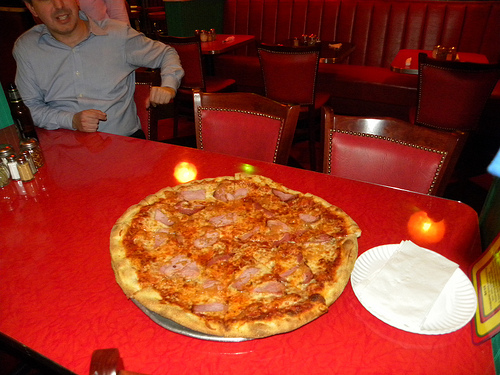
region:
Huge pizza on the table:
[94, 148, 367, 354]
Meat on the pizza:
[159, 214, 263, 295]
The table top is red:
[16, 233, 177, 357]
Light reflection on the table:
[395, 184, 478, 259]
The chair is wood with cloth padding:
[312, 98, 462, 178]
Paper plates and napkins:
[358, 228, 472, 338]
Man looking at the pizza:
[22, 3, 199, 176]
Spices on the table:
[9, 128, 56, 180]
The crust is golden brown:
[263, 295, 327, 332]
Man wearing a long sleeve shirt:
[42, 30, 142, 101]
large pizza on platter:
[132, 156, 321, 371]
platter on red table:
[126, 179, 325, 356]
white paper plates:
[372, 227, 454, 321]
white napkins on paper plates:
[368, 252, 452, 319]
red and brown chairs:
[210, 79, 465, 189]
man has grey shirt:
[0, 16, 166, 137]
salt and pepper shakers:
[0, 152, 45, 192]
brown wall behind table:
[212, 1, 449, 71]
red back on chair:
[192, 106, 283, 173]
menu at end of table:
[450, 232, 495, 310]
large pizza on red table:
[100, 163, 337, 316]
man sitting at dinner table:
[0, 19, 132, 114]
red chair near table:
[198, 96, 291, 153]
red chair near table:
[322, 107, 468, 197]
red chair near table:
[416, 41, 495, 143]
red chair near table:
[248, 45, 337, 105]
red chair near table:
[159, 34, 211, 89]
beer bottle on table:
[17, 81, 34, 153]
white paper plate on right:
[348, 227, 469, 326]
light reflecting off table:
[175, 152, 217, 187]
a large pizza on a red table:
[95, 144, 369, 335]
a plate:
[350, 229, 483, 341]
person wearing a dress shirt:
[10, 3, 195, 161]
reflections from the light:
[155, 155, 205, 187]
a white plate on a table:
[350, 221, 491, 351]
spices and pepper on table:
[0, 122, 53, 184]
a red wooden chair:
[185, 90, 305, 171]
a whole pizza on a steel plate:
[105, 171, 363, 341]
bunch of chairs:
[147, 28, 498, 198]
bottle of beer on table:
[4, 79, 61, 151]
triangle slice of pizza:
[218, 240, 323, 342]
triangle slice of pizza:
[121, 186, 224, 249]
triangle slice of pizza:
[111, 214, 210, 302]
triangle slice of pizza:
[151, 238, 240, 343]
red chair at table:
[314, 103, 466, 217]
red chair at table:
[179, 76, 314, 178]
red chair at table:
[401, 46, 498, 143]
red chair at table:
[249, 38, 336, 122]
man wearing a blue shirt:
[9, 21, 189, 151]